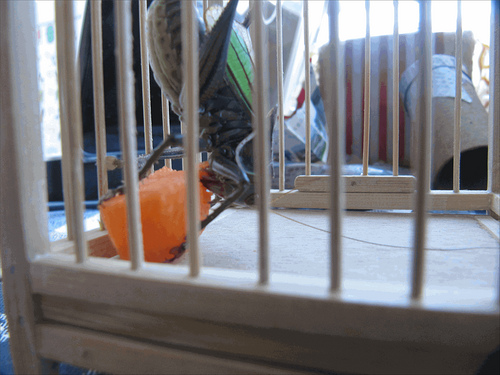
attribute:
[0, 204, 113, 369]
floor — blue. 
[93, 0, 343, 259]
bug — eating. 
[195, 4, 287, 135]
wing —  green. 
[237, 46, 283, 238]
rod — wooden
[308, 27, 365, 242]
rod — wooden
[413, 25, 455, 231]
rod — wooden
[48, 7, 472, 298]
cage — brown, wooden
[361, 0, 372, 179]
rod — wooden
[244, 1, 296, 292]
rod — wooden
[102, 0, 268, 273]
bug — holding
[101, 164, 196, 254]
food —  orange.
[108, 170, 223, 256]
fruit orange — sliced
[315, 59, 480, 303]
cage — white  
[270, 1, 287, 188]
rod — wooden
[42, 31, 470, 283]
bars — white. 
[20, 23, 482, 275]
cage — blue, under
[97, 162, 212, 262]
cube — sliced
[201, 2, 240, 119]
legs — bent.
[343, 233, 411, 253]
long antenna — long. 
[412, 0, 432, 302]
rod — wooden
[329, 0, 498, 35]
window — shining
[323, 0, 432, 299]
bars — cage, wooden, brown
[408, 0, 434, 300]
rod — wooden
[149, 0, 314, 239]
bug — eating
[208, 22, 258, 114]
wing — green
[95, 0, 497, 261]
bug — upside down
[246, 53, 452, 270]
antennae — long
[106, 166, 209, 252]
fruit — piece. 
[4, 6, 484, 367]
cage — light wood